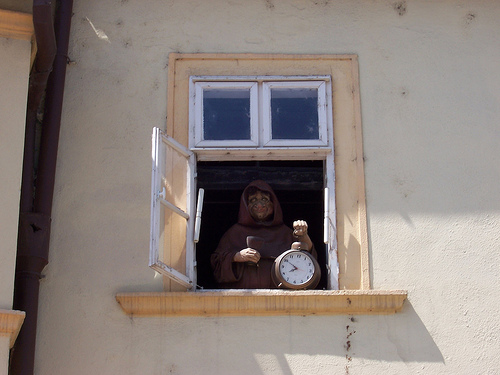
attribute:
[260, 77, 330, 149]
window — wooden, small, white, transparent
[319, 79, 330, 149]
frame — wooden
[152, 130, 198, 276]
window — open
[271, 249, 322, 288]
clock — white, large, round, brown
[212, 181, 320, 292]
manequin — old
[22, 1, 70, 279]
beam — dark, vertical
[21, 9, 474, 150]
building — beige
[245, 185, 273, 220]
face — scary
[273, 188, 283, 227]
hood — long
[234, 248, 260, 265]
hand — brown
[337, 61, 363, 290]
frame — brown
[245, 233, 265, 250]
cup — wooden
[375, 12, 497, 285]
wall — white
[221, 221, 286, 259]
robe — brown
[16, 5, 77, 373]
pipe — brown